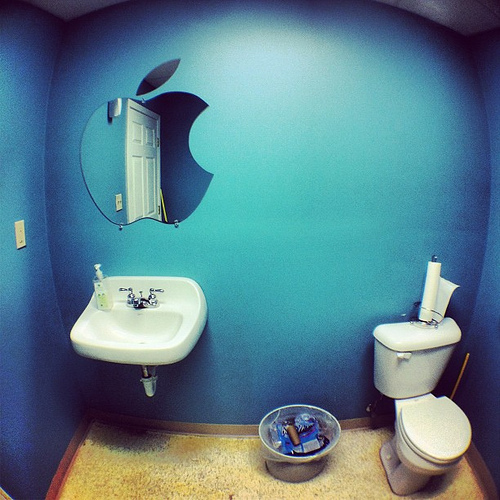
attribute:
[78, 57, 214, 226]
mirror — glass, apple shaped, large, apple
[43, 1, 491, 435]
wall — painted, blue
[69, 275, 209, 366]
sink — white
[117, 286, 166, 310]
faucet — silver, metal, not running, white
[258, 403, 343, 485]
garbage can — bag lined, full, trash can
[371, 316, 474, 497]
toilet — white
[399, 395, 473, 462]
lid — closed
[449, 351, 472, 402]
plunger handle — brown, toilet plunger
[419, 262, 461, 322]
roll — white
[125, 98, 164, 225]
door reflection — white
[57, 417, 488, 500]
floor — dirty, linoleum, yellow, tiled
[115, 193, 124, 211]
light switch — off white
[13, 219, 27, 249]
switch — beige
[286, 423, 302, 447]
toilet paper roll — empty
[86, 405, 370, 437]
floor board — brown